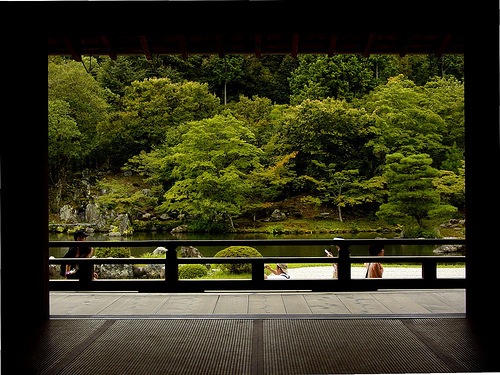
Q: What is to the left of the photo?
A: Bright green trees beside a pond.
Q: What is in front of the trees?
A: Water.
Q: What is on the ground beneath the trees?
A: Grass.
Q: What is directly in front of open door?
A: A sidewalk.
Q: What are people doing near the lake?
A: Walking.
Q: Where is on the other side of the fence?
A: A bush.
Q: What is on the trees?
A: Green leaves.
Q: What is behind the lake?
A: Forest of trees.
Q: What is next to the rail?
A: A walkway.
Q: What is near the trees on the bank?
A: The lake.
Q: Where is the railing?
A: Next to the path.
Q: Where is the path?
A: Near the railing.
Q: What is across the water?
A: A forest.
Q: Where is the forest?
A: Across the water.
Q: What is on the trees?
A: Leaves.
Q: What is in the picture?
A: Trees.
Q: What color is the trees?
A: Green.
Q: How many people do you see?
A: Five.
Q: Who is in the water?
A: Nobody.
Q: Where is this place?
A: The forest.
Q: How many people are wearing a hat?
A: Two.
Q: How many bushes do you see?
A: Two.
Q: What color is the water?
A: Green.